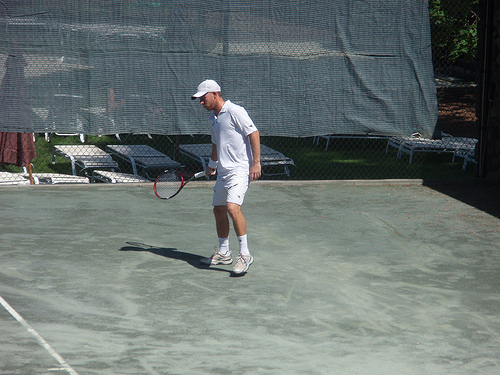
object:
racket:
[152, 167, 215, 200]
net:
[0, 0, 484, 186]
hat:
[190, 78, 221, 101]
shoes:
[231, 252, 255, 276]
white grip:
[192, 168, 214, 179]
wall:
[0, 0, 500, 185]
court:
[0, 176, 500, 375]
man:
[188, 77, 264, 276]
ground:
[0, 65, 500, 375]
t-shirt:
[207, 98, 259, 181]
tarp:
[1, 1, 439, 141]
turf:
[0, 58, 500, 185]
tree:
[425, 0, 480, 75]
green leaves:
[468, 29, 475, 38]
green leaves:
[455, 47, 462, 56]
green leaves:
[430, 9, 444, 20]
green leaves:
[448, 5, 458, 13]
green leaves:
[433, 38, 441, 48]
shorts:
[211, 172, 250, 208]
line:
[0, 298, 81, 375]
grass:
[0, 131, 500, 180]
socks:
[234, 232, 250, 257]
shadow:
[118, 239, 248, 280]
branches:
[467, 6, 482, 22]